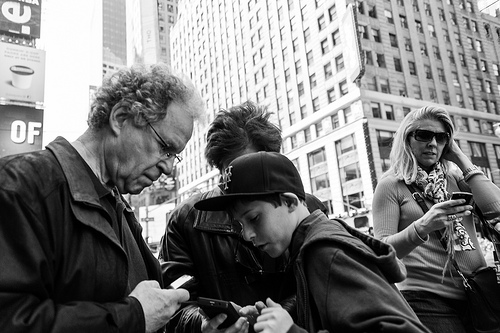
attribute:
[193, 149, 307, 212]
baseball hat — black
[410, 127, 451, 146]
sunglasses — black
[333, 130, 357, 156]
window — closed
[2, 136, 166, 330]
jacket — black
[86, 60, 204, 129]
hair — curly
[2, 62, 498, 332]
people — standing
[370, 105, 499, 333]
woman — standing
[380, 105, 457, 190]
hair — blonde